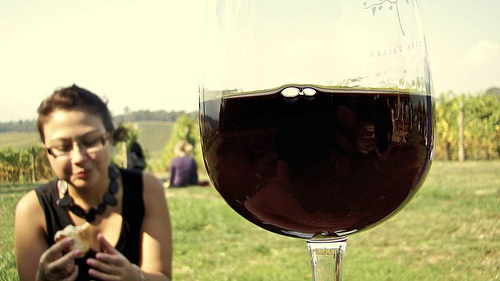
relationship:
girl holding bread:
[12, 83, 177, 281] [52, 221, 102, 259]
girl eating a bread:
[12, 83, 177, 281] [52, 221, 102, 259]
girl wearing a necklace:
[12, 83, 177, 281] [56, 177, 126, 226]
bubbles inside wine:
[281, 86, 301, 98] [190, 35, 438, 281]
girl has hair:
[12, 83, 177, 281] [167, 140, 198, 191]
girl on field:
[12, 83, 177, 281] [0, 153, 500, 281]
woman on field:
[162, 141, 200, 191] [0, 153, 500, 281]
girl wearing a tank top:
[12, 83, 177, 281] [31, 165, 146, 281]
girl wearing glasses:
[12, 83, 177, 281] [40, 130, 114, 159]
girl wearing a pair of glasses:
[12, 83, 177, 281] [40, 130, 114, 159]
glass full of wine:
[188, 41, 443, 281] [190, 35, 438, 281]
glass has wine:
[188, 41, 443, 281] [190, 35, 438, 281]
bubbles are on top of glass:
[281, 84, 321, 101] [188, 41, 443, 281]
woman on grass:
[162, 137, 210, 189] [16, 193, 487, 281]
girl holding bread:
[12, 83, 177, 281] [58, 225, 107, 248]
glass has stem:
[188, 41, 443, 281] [306, 240, 344, 280]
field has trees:
[4, 153, 498, 280] [419, 82, 499, 165]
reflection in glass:
[220, 102, 415, 232] [188, 41, 443, 281]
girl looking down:
[12, 83, 177, 281] [12, 202, 165, 280]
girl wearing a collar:
[12, 83, 177, 281] [56, 177, 126, 226]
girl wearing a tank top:
[12, 83, 177, 281] [31, 172, 147, 276]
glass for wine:
[188, 41, 443, 281] [190, 35, 438, 281]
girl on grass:
[12, 86, 174, 280] [16, 193, 487, 281]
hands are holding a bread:
[28, 237, 139, 281] [52, 221, 102, 259]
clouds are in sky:
[9, 30, 165, 93] [2, 3, 500, 119]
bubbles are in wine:
[281, 84, 321, 101] [190, 35, 438, 281]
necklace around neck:
[56, 177, 126, 226] [59, 173, 120, 206]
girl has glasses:
[12, 83, 177, 281] [40, 130, 114, 159]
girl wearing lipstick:
[12, 83, 177, 281] [71, 170, 91, 180]